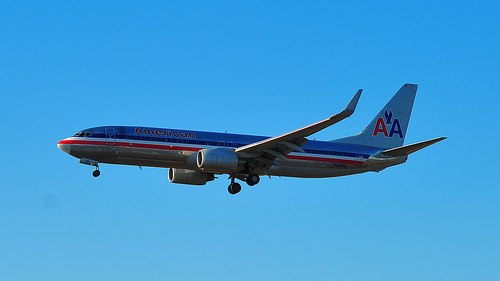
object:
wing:
[373, 136, 447, 160]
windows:
[304, 148, 356, 156]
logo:
[371, 107, 403, 139]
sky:
[387, 189, 474, 258]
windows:
[75, 130, 92, 138]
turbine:
[194, 145, 240, 174]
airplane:
[57, 82, 448, 195]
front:
[56, 125, 148, 166]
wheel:
[225, 181, 243, 196]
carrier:
[57, 82, 447, 194]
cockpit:
[70, 125, 121, 137]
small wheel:
[91, 169, 100, 178]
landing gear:
[226, 170, 263, 195]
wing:
[237, 88, 366, 152]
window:
[188, 140, 228, 146]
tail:
[362, 82, 448, 173]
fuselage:
[56, 125, 405, 179]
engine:
[194, 146, 242, 172]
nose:
[58, 133, 74, 156]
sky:
[2, 0, 481, 279]